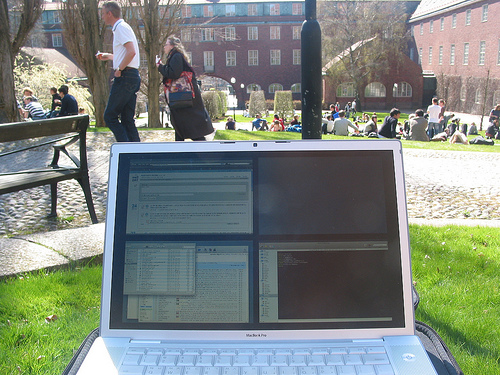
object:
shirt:
[112, 18, 140, 69]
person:
[332, 110, 359, 136]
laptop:
[73, 139, 439, 375]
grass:
[1, 224, 500, 374]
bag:
[169, 91, 193, 108]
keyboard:
[108, 345, 396, 375]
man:
[427, 98, 444, 141]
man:
[409, 109, 430, 141]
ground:
[401, 148, 500, 226]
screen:
[109, 149, 404, 329]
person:
[378, 107, 402, 139]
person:
[56, 87, 78, 116]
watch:
[117, 66, 122, 71]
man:
[94, 0, 141, 143]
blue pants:
[103, 66, 141, 141]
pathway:
[0, 129, 500, 277]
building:
[0, 0, 499, 120]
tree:
[57, 0, 139, 127]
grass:
[214, 110, 500, 154]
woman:
[156, 34, 215, 141]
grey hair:
[102, 2, 121, 19]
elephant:
[88, 129, 414, 369]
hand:
[114, 70, 121, 77]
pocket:
[112, 74, 125, 88]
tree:
[315, 0, 410, 112]